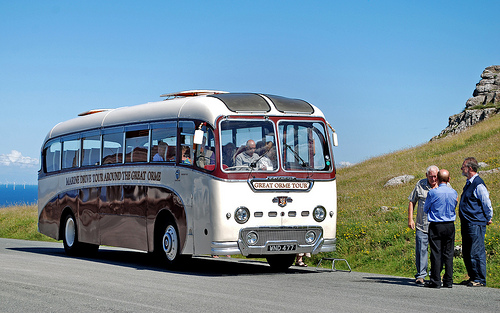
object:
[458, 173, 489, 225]
vest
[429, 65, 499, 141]
mountain peak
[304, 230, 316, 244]
lights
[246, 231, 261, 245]
lights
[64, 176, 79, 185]
word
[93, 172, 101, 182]
word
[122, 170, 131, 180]
word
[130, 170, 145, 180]
word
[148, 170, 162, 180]
word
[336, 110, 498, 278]
grass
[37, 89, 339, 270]
bus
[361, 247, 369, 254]
dandylions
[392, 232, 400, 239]
dandylions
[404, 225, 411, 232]
dandylions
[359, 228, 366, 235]
dandylions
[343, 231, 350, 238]
dandylions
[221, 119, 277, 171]
window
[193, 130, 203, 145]
mirror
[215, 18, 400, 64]
sky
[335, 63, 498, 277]
hill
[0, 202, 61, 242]
grass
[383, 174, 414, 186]
boulder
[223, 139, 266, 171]
people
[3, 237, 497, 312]
road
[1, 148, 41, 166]
peak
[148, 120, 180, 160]
window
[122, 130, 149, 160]
window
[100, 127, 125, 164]
window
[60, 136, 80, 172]
window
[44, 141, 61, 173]
window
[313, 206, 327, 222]
light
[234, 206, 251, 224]
light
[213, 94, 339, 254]
front